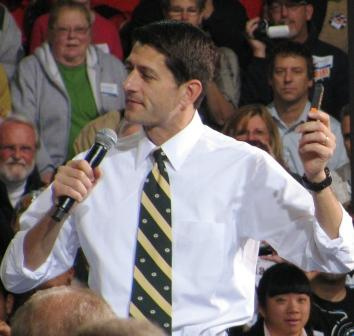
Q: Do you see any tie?
A: Yes, there is a tie.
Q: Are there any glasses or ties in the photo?
A: Yes, there is a tie.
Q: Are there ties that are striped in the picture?
A: Yes, there is a striped tie.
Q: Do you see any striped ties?
A: Yes, there is a striped tie.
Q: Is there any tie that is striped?
A: Yes, there is a tie that is striped.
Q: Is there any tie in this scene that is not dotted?
A: Yes, there is a striped tie.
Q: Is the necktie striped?
A: Yes, the necktie is striped.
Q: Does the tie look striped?
A: Yes, the tie is striped.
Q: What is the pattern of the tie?
A: The tie is striped.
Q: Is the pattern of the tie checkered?
A: No, the tie is striped.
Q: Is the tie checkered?
A: No, the tie is striped.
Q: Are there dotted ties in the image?
A: No, there is a tie but it is striped.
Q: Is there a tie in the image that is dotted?
A: No, there is a tie but it is striped.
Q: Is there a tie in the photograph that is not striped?
A: No, there is a tie but it is striped.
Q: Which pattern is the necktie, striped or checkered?
A: The necktie is striped.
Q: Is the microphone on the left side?
A: Yes, the microphone is on the left of the image.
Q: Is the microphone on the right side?
A: No, the microphone is on the left of the image.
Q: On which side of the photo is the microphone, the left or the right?
A: The microphone is on the left of the image.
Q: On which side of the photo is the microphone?
A: The microphone is on the left of the image.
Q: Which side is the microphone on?
A: The microphone is on the left of the image.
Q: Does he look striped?
A: Yes, the man is striped.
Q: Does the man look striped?
A: Yes, the man is striped.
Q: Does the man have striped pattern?
A: Yes, the man is striped.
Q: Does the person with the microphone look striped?
A: Yes, the man is striped.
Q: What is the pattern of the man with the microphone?
A: The man is striped.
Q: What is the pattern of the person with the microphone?
A: The man is striped.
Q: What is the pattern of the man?
A: The man is striped.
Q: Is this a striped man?
A: Yes, this is a striped man.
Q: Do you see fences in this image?
A: No, there are no fences.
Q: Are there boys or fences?
A: No, there are no fences or boys.